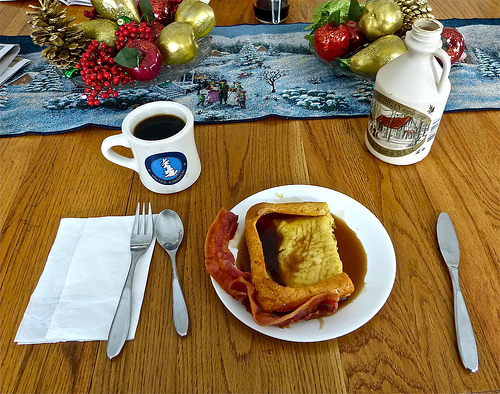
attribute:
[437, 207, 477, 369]
knife — silver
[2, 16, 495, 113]
table runner — blue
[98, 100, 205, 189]
mug — white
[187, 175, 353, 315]
toast — french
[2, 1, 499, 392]
table — wooden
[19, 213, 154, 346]
napkin — white, paper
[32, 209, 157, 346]
napkin — paper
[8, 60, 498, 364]
table — brown